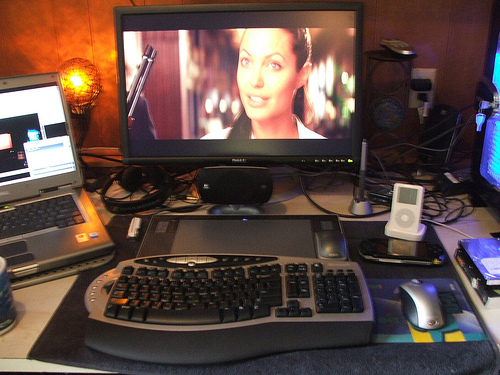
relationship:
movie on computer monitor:
[122, 14, 353, 153] [106, 4, 363, 169]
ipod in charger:
[386, 180, 423, 230] [388, 230, 420, 240]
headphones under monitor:
[100, 161, 171, 209] [122, 14, 353, 153]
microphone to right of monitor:
[349, 139, 374, 219] [122, 14, 353, 153]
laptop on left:
[1, 68, 115, 263] [2, 74, 72, 146]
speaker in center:
[194, 163, 277, 210] [199, 163, 261, 177]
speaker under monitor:
[194, 163, 277, 210] [106, 4, 363, 169]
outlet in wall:
[411, 66, 439, 114] [424, 2, 475, 59]